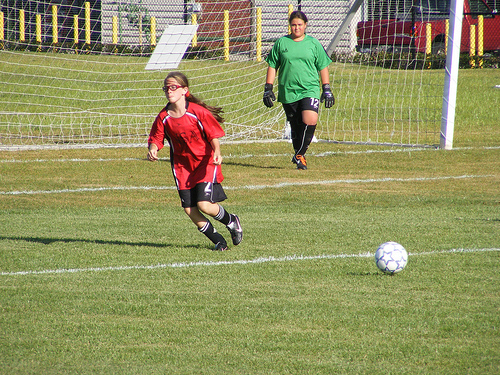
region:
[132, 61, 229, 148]
girl is wearing eyeglasses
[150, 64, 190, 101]
girl is wearing eyeglasses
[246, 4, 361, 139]
girl is wearing gloves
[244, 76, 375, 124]
girl is wearing gloves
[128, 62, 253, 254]
Girl in red uniform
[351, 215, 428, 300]
Blue and white soccer ball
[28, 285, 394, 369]
Green grassy playing field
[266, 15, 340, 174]
Number 12 in green uniform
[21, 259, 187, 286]
White yard line on field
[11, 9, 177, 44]
Yellow parking poles behind field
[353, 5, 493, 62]
Red pickup truck parked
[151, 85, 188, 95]
Red glasses on face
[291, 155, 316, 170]
Orange soccer shoes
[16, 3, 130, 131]
Goal net behind players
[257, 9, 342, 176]
chubby girl in green shirt defending the net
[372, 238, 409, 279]
soccer ball on the field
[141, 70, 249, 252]
little girl in red shirt playing soccer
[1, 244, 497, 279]
white line in the grass near ball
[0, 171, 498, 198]
white line in the grass closer to net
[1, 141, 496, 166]
white line in grass flush with the net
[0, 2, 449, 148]
soccer net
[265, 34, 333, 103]
green shirt on the chubby girl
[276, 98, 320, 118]
black shorts on the chubby girl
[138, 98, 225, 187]
soccer players red shirt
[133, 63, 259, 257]
The girl is running.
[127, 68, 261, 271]
The girl has long hair.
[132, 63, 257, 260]
The girl is wearing glasses.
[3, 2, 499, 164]
The netting is white.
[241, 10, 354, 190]
The girl is standing.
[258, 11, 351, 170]
The girl is wearing gloves.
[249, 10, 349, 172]
The girl is wearing a green shirt.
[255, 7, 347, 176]
The girl's shirt has short sleeves.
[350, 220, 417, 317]
The ball is round.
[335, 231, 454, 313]
The ball is black and white.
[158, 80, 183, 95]
the glasses are red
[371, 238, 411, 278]
the ball is white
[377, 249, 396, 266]
the ball has stars on it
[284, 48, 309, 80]
the shirt is green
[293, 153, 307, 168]
the shoelaces are orange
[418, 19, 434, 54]
the pole is yellow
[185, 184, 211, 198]
the shorts are black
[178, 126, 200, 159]
the shirt is red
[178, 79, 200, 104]
her hair is in a ponytail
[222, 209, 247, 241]
the shoes are black